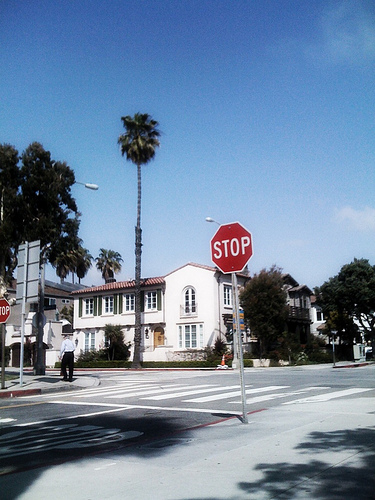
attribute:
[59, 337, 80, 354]
sleeves — white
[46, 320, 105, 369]
sleeves — white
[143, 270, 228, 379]
house — white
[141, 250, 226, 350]
house — white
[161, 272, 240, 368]
house — white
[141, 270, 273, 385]
house — white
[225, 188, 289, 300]
sign — red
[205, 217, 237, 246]
sign — red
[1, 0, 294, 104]
sky — cloudless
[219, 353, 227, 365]
traffic cone — orange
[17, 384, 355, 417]
crossing walk — white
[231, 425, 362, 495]
shadow — trees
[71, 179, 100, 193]
street light — off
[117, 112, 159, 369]
palm tree — tall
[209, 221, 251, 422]
stop sign — one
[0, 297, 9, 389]
stop sign — one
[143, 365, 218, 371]
curve — red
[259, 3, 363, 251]
sky — blue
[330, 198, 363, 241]
cloud — one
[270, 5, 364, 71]
cloud — one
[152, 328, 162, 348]
door — wood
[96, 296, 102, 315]
shutter — green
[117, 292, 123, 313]
shutter — green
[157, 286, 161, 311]
shutter — green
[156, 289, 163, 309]
shutter — green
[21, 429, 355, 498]
pavement — grey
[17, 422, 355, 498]
pavement — grey